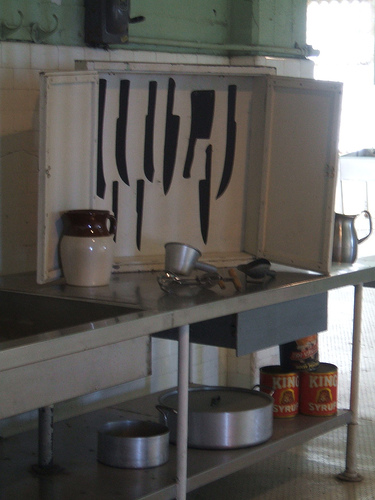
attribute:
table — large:
[2, 247, 373, 498]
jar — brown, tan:
[63, 194, 126, 289]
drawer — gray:
[152, 290, 328, 357]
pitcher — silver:
[334, 211, 372, 271]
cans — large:
[258, 339, 342, 420]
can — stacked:
[257, 365, 298, 417]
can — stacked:
[297, 361, 338, 414]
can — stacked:
[276, 325, 321, 371]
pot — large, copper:
[154, 231, 242, 296]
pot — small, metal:
[157, 239, 205, 269]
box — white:
[36, 53, 346, 283]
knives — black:
[99, 78, 242, 246]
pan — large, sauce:
[147, 362, 286, 447]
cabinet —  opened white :
[43, 62, 93, 278]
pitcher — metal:
[330, 209, 371, 263]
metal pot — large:
[192, 380, 281, 445]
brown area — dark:
[60, 208, 116, 235]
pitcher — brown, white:
[60, 208, 118, 285]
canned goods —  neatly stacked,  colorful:
[244, 362, 340, 413]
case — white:
[97, 77, 249, 246]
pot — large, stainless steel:
[153, 379, 281, 454]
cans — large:
[259, 332, 339, 420]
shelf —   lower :
[4, 412, 175, 497]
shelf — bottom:
[54, 261, 361, 316]